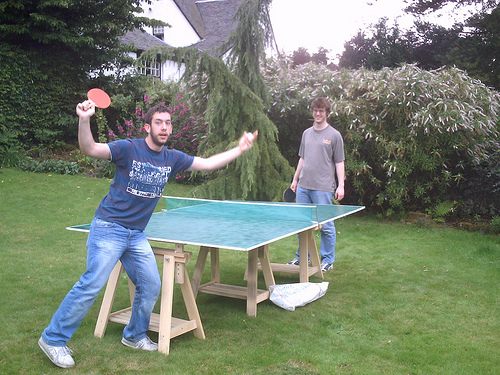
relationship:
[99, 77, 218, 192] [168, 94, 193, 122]
bush covered in flowers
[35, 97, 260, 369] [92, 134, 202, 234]
man wears shirt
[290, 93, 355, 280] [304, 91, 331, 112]
man has hair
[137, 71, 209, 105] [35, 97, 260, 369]
flowers behind man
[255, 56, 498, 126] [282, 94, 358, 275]
bush behind man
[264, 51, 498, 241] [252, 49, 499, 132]
bush has flowers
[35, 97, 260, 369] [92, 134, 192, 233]
man wearing shirt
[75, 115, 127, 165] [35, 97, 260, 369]
arm belonging to man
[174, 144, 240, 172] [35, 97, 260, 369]
arm belonging to man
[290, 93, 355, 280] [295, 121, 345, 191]
man wearing shirt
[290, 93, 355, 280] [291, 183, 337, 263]
man wearing jeans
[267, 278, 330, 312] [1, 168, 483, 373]
bag lying on top of grass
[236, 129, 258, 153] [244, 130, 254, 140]
hand holding ball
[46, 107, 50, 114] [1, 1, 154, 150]
leaf growing on tree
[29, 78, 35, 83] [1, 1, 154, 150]
leaf growing on tree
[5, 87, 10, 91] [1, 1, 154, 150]
leaf growing on tree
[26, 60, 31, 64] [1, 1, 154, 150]
leaf growing on tree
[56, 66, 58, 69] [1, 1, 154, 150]
leaf growing on tree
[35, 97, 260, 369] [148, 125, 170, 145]
man growing beard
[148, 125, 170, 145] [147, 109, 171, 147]
beard growing on face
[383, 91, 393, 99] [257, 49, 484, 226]
flower blooming on bush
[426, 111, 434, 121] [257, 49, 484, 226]
flower blooming on bush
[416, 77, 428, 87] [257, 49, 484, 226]
flower blooming on bush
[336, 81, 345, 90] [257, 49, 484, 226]
flower blooming on bush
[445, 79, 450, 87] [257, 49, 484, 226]
flower blooming on bush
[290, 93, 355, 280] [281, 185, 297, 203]
man holding paddle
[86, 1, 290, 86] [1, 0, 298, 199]
house standing behind greenery